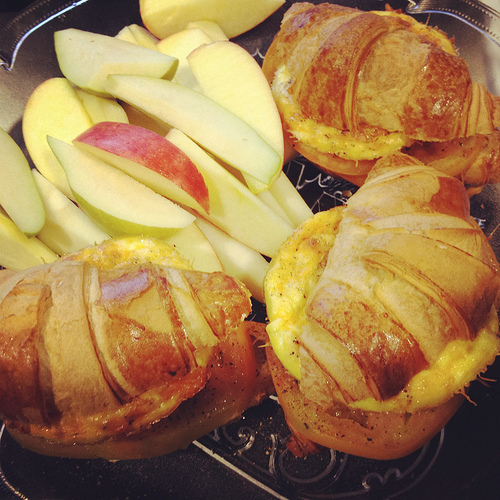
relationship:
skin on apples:
[80, 59, 194, 215] [10, 36, 294, 282]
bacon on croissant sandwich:
[10, 269, 181, 426] [0, 245, 256, 459]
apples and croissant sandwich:
[10, 36, 294, 282] [269, 3, 497, 191]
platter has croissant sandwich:
[6, 9, 498, 486] [0, 245, 256, 459]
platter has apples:
[6, 9, 498, 486] [10, 36, 294, 282]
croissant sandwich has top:
[269, 3, 497, 191] [279, 8, 476, 136]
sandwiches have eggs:
[10, 12, 495, 469] [270, 221, 487, 405]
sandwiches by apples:
[10, 12, 495, 469] [10, 36, 294, 282]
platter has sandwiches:
[6, 9, 498, 486] [10, 12, 495, 469]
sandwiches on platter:
[10, 12, 495, 469] [6, 9, 498, 486]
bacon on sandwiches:
[10, 269, 181, 426] [10, 12, 495, 469]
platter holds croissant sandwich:
[6, 9, 498, 486] [269, 3, 497, 191]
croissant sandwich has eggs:
[269, 3, 497, 191] [270, 221, 487, 405]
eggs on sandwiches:
[270, 221, 487, 405] [10, 12, 495, 469]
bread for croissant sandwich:
[298, 158, 473, 392] [269, 3, 497, 191]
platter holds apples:
[6, 9, 498, 486] [10, 36, 294, 282]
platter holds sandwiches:
[6, 9, 498, 486] [10, 12, 495, 469]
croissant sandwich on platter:
[269, 3, 497, 191] [6, 9, 498, 486]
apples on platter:
[10, 36, 294, 282] [6, 9, 498, 486]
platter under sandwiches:
[6, 9, 498, 486] [10, 12, 495, 469]